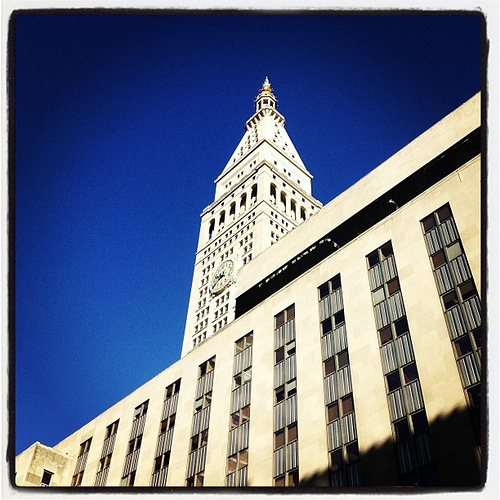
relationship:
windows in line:
[312, 261, 359, 492] [261, 297, 314, 484]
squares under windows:
[317, 292, 349, 319] [312, 261, 359, 492]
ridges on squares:
[317, 326, 352, 363] [317, 292, 349, 319]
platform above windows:
[234, 89, 486, 324] [312, 261, 359, 492]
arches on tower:
[191, 154, 331, 273] [179, 72, 339, 366]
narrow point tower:
[208, 56, 322, 291] [179, 72, 339, 366]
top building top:
[231, 71, 306, 163] [231, 65, 311, 164]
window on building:
[270, 300, 303, 428] [316, 276, 353, 404]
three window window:
[261, 297, 314, 484] [270, 300, 303, 428]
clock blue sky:
[209, 258, 236, 297] [19, 32, 201, 211]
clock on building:
[204, 242, 244, 307] [316, 276, 353, 404]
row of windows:
[415, 199, 480, 428] [312, 261, 359, 492]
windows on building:
[312, 261, 359, 492] [316, 276, 353, 404]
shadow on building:
[303, 388, 479, 487] [17, 71, 487, 489]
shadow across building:
[303, 388, 479, 487] [316, 276, 353, 404]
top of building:
[231, 65, 311, 164] [316, 276, 353, 404]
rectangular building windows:
[17, 71, 487, 489] [312, 261, 359, 492]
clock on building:
[204, 242, 244, 307] [17, 71, 487, 489]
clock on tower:
[204, 242, 244, 307] [179, 72, 339, 366]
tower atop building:
[179, 72, 339, 366] [17, 71, 487, 489]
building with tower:
[17, 71, 487, 489] [179, 72, 339, 366]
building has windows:
[316, 276, 353, 404] [312, 261, 359, 492]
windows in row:
[312, 261, 359, 492] [415, 199, 480, 428]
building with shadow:
[17, 71, 487, 489] [303, 388, 479, 487]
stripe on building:
[234, 89, 486, 324] [17, 71, 487, 489]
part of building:
[18, 394, 87, 493] [17, 71, 487, 489]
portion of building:
[208, 56, 322, 291] [17, 71, 487, 489]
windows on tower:
[174, 163, 262, 345] [179, 72, 339, 366]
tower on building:
[179, 72, 339, 366] [17, 71, 487, 489]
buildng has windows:
[17, 71, 487, 489] [312, 261, 359, 492]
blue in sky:
[31, 28, 453, 67] [19, 32, 201, 211]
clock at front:
[204, 242, 244, 307] [184, 228, 262, 345]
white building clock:
[17, 71, 487, 489] [204, 242, 244, 307]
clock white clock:
[209, 258, 236, 297] [204, 242, 244, 307]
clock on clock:
[209, 258, 236, 297] [204, 242, 244, 307]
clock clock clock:
[209, 258, 236, 297] [209, 258, 236, 297]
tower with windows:
[179, 72, 339, 366] [174, 163, 262, 345]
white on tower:
[17, 71, 487, 489] [179, 72, 339, 366]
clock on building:
[179, 72, 339, 366] [70, 95, 476, 497]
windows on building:
[17, 71, 487, 489] [70, 95, 476, 497]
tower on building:
[179, 72, 339, 366] [34, 80, 469, 486]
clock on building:
[179, 72, 339, 366] [34, 80, 469, 486]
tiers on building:
[179, 72, 339, 366] [34, 80, 469, 486]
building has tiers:
[34, 80, 469, 486] [179, 72, 339, 366]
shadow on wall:
[303, 388, 479, 487] [309, 297, 439, 465]